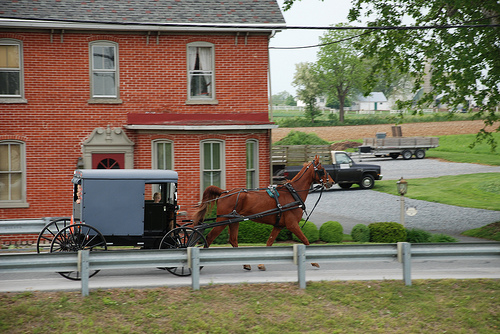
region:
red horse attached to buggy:
[188, 152, 334, 267]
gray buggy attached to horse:
[70, 167, 177, 241]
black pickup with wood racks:
[270, 143, 382, 189]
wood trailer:
[361, 131, 441, 159]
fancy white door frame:
[80, 121, 135, 169]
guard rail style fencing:
[0, 241, 498, 293]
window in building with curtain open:
[185, 39, 216, 104]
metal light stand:
[397, 175, 408, 243]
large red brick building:
[2, 1, 278, 238]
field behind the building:
[272, 123, 499, 142]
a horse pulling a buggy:
[201, 160, 341, 272]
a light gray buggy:
[40, 161, 206, 282]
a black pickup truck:
[290, 137, 382, 185]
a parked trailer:
[359, 123, 446, 163]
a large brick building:
[15, 15, 258, 232]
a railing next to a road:
[15, 256, 485, 303]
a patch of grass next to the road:
[15, 294, 459, 324]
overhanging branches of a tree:
[395, 12, 497, 119]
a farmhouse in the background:
[305, 73, 431, 130]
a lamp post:
[390, 166, 424, 228]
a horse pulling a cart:
[187, 146, 338, 277]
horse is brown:
[191, 150, 338, 265]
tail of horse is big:
[188, 177, 228, 226]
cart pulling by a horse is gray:
[26, 155, 215, 280]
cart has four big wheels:
[33, 159, 212, 284]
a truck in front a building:
[264, 133, 388, 192]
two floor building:
[5, 2, 279, 194]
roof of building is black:
[0, 0, 284, 37]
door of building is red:
[81, 143, 136, 167]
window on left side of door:
[1, 135, 35, 213]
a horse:
[233, 117, 350, 332]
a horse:
[274, 179, 356, 305]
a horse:
[223, 127, 294, 232]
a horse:
[243, 171, 296, 248]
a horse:
[240, 74, 325, 276]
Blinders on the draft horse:
[310, 165, 330, 175]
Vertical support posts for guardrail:
[395, 233, 415, 286]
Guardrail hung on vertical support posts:
[309, 242, 388, 265]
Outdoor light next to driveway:
[388, 173, 419, 235]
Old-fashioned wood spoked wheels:
[56, 222, 108, 282]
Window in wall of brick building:
[182, 42, 227, 108]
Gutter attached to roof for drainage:
[25, 16, 289, 38]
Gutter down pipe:
[263, 24, 282, 171]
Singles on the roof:
[140, 6, 232, 23]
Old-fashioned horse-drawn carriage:
[37, 166, 211, 276]